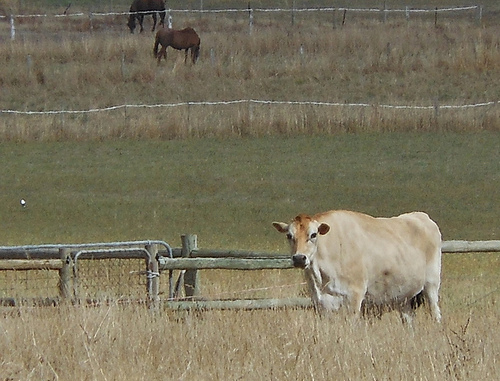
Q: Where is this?
A: This is at the field.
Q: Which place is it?
A: It is a field.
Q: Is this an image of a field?
A: Yes, it is showing a field.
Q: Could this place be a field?
A: Yes, it is a field.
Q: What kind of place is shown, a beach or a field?
A: It is a field.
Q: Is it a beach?
A: No, it is a field.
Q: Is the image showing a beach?
A: No, the picture is showing a field.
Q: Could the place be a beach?
A: No, it is a field.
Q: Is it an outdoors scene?
A: Yes, it is outdoors.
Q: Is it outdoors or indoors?
A: It is outdoors.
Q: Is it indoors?
A: No, it is outdoors.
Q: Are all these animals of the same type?
A: No, there are both horses and birds.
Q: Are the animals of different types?
A: Yes, they are horses and birds.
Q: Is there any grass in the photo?
A: Yes, there is grass.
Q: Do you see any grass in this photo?
A: Yes, there is grass.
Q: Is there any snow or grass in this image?
A: Yes, there is grass.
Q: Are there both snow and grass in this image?
A: No, there is grass but no snow.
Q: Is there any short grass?
A: Yes, there is short grass.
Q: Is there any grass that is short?
A: Yes, there is grass that is short.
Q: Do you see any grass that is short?
A: Yes, there is grass that is short.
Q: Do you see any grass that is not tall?
A: Yes, there is short grass.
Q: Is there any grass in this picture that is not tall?
A: Yes, there is short grass.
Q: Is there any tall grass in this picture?
A: Yes, there is tall grass.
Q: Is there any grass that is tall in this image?
A: Yes, there is tall grass.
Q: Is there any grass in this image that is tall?
A: Yes, there is grass that is tall.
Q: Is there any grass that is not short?
A: Yes, there is tall grass.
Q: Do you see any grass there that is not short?
A: Yes, there is tall grass.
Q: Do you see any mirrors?
A: No, there are no mirrors.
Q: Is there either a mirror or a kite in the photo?
A: No, there are no mirrors or kites.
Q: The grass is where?
A: The grass is in the field.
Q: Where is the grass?
A: The grass is in the field.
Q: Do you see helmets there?
A: No, there are no helmets.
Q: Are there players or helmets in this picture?
A: No, there are no helmets or players.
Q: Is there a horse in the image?
A: Yes, there is a horse.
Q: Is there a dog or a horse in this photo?
A: Yes, there is a horse.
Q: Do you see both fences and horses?
A: Yes, there are both a horse and a fence.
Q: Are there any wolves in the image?
A: No, there are no wolves.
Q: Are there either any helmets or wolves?
A: No, there are no wolves or helmets.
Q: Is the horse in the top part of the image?
A: Yes, the horse is in the top of the image.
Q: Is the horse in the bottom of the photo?
A: No, the horse is in the top of the image.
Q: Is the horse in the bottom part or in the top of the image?
A: The horse is in the top of the image.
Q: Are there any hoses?
A: No, there are no hoses.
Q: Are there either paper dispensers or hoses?
A: No, there are no hoses or paper dispensers.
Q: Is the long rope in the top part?
A: Yes, the rope is in the top of the image.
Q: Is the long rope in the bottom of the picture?
A: No, the rope is in the top of the image.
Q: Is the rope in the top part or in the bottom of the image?
A: The rope is in the top of the image.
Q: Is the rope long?
A: Yes, the rope is long.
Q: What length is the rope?
A: The rope is long.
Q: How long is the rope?
A: The rope is long.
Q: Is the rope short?
A: No, the rope is long.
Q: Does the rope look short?
A: No, the rope is long.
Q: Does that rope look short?
A: No, the rope is long.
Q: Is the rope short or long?
A: The rope is long.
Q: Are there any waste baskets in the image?
A: No, there are no waste baskets.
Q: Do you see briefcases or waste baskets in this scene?
A: No, there are no waste baskets or briefcases.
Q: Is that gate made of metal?
A: Yes, the gate is made of metal.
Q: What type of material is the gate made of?
A: The gate is made of metal.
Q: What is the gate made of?
A: The gate is made of metal.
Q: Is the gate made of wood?
A: No, the gate is made of metal.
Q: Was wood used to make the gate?
A: No, the gate is made of metal.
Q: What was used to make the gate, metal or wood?
A: The gate is made of metal.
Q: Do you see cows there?
A: Yes, there is a cow.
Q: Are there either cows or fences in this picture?
A: Yes, there is a cow.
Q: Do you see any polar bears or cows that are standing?
A: Yes, the cow is standing.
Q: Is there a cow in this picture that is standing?
A: Yes, there is a cow that is standing.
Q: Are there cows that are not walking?
A: Yes, there is a cow that is standing.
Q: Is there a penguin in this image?
A: No, there are no penguins.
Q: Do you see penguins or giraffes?
A: No, there are no penguins or giraffes.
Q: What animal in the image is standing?
A: The animal is a cow.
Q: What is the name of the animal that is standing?
A: The animal is a cow.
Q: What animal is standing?
A: The animal is a cow.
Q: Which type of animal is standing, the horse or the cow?
A: The cow is standing.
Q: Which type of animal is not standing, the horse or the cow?
A: The horse is not standing.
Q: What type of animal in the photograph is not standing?
A: The animal is a horse.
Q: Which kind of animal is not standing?
A: The animal is a horse.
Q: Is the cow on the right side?
A: Yes, the cow is on the right of the image.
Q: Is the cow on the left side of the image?
A: No, the cow is on the right of the image.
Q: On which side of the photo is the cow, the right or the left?
A: The cow is on the right of the image.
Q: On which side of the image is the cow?
A: The cow is on the right of the image.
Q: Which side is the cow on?
A: The cow is on the right of the image.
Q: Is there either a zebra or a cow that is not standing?
A: No, there is a cow but it is standing.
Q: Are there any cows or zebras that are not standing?
A: No, there is a cow but it is standing.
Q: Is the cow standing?
A: Yes, the cow is standing.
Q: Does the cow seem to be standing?
A: Yes, the cow is standing.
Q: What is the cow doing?
A: The cow is standing.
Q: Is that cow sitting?
A: No, the cow is standing.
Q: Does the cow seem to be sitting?
A: No, the cow is standing.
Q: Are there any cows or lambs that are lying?
A: No, there is a cow but it is standing.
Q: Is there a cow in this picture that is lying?
A: No, there is a cow but it is standing.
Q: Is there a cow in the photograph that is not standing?
A: No, there is a cow but it is standing.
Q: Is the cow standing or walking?
A: The cow is standing.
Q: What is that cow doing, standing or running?
A: The cow is standing.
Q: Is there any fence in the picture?
A: Yes, there is a fence.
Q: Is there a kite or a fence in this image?
A: Yes, there is a fence.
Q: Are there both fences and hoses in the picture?
A: No, there is a fence but no hoses.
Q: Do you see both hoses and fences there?
A: No, there is a fence but no hoses.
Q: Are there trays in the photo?
A: No, there are no trays.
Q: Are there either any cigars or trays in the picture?
A: No, there are no trays or cigars.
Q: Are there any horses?
A: Yes, there is a horse.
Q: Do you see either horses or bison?
A: Yes, there is a horse.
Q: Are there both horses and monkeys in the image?
A: No, there is a horse but no monkeys.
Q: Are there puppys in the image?
A: No, there are no puppys.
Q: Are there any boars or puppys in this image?
A: No, there are no puppys or boars.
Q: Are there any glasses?
A: No, there are no glasses.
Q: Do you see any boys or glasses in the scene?
A: No, there are no glasses or boys.